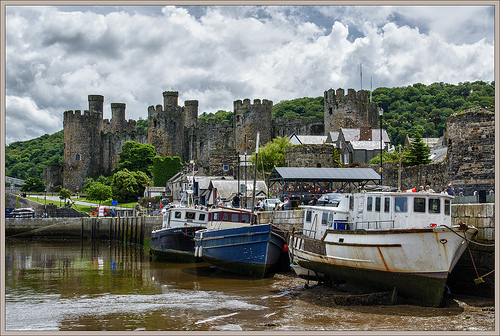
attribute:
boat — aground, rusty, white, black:
[278, 167, 479, 311]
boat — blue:
[189, 189, 288, 272]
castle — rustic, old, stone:
[53, 88, 500, 212]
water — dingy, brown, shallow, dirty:
[3, 233, 499, 336]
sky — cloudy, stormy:
[5, 6, 500, 147]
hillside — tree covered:
[4, 129, 69, 185]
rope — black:
[440, 221, 499, 261]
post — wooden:
[138, 215, 144, 247]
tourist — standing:
[438, 185, 450, 199]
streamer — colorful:
[267, 181, 318, 198]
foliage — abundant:
[77, 132, 165, 207]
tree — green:
[109, 168, 155, 206]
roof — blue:
[265, 164, 378, 188]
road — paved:
[23, 191, 140, 215]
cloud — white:
[351, 19, 493, 90]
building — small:
[199, 177, 269, 209]